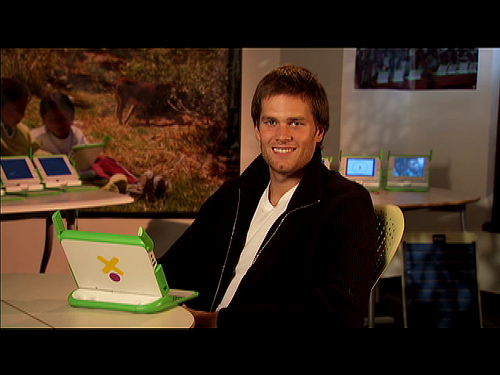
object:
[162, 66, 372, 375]
man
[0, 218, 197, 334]
table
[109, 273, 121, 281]
dot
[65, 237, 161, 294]
back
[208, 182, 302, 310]
shirt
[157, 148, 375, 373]
jacket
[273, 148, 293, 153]
teeth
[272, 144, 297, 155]
mouth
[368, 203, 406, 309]
chair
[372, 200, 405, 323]
back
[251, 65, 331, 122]
hair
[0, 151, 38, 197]
laptop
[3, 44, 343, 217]
wall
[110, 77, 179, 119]
animal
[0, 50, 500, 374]
lab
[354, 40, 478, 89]
photo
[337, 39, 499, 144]
wall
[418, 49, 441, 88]
monkey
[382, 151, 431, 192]
computers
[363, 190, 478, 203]
table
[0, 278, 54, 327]
line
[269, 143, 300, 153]
smile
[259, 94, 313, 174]
face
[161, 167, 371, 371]
body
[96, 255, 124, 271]
cross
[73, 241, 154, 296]
cover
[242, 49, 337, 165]
wall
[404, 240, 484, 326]
bin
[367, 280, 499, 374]
ground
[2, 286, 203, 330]
hunk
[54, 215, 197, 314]
computer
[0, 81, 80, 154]
children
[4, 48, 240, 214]
photo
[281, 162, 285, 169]
dimple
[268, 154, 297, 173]
chin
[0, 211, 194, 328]
desk